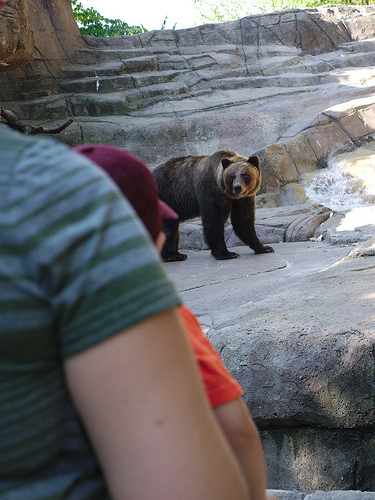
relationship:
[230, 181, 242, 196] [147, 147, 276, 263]
nose of bear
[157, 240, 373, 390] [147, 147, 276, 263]
ground in front of bear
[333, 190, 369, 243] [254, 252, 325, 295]
light hitting ground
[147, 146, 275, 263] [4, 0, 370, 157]
bear in exhibit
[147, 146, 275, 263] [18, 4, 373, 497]
bear on rocks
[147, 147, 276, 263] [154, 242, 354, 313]
bear on rocks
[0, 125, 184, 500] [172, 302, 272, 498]
shirt on arm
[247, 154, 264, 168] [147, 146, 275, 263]
ear. of bear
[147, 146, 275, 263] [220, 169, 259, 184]
bear has eyes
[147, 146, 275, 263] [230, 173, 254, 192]
bear has nose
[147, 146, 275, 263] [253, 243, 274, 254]
bear has paw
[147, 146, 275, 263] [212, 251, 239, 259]
bear has paw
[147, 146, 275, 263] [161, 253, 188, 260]
bear has paw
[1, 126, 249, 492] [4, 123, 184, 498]
person wearing shirt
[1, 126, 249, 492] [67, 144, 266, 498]
person wearing shirt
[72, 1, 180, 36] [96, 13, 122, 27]
tree with leaves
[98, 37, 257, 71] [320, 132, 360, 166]
stick on rocks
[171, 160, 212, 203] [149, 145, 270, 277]
fur of bear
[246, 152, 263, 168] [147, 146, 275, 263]
ear of bear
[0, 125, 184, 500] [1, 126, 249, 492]
shirt on person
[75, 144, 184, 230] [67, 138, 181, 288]
cap on head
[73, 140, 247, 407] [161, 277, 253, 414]
boy wearing shirt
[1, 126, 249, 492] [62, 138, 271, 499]
person holding boy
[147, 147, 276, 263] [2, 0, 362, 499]
bear at zoo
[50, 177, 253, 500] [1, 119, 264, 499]
arm of woman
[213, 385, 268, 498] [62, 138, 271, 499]
arm of boy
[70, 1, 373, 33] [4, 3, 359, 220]
trees behind rocks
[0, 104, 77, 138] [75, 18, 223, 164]
branch on rocks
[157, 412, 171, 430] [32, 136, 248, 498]
spot on arm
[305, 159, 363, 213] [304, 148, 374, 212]
foam on water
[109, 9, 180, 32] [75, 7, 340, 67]
light in background